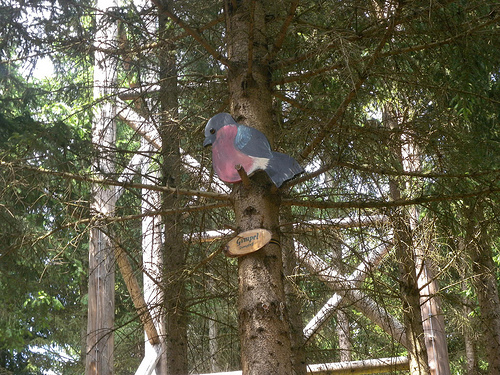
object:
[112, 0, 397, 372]
pine tree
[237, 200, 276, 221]
wood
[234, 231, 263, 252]
wood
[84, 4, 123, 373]
beam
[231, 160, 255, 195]
branch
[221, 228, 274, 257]
sign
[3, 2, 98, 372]
tree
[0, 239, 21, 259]
leaves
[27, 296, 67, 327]
leaves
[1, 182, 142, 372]
tree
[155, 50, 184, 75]
leaves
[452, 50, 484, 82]
leaves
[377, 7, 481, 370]
tree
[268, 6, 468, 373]
tree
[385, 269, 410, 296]
leaves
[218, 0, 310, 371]
tree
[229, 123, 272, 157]
wing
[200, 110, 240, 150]
head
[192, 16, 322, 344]
tree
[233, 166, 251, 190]
perch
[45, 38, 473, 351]
forest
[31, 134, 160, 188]
branches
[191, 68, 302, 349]
tree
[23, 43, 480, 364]
forest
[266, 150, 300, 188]
tail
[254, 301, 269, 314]
bark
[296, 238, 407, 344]
cross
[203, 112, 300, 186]
bird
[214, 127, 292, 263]
trunk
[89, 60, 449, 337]
framework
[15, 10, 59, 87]
sky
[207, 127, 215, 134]
eye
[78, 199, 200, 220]
branch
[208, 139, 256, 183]
belly